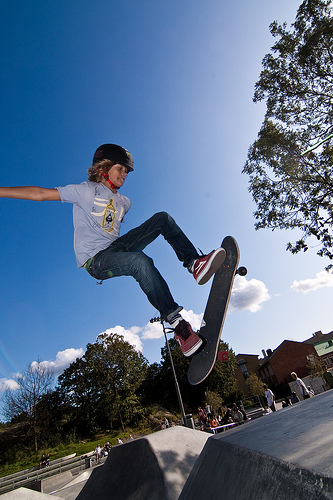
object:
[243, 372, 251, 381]
window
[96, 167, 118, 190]
chin strap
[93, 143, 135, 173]
helmet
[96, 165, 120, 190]
strap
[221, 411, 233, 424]
people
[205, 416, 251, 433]
bleachers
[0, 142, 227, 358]
boy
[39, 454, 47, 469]
person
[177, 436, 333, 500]
skateboard ramp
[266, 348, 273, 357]
chimney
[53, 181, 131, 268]
blue teeshirt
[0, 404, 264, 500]
stands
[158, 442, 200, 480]
shadow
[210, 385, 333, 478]
ramp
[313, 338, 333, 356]
roof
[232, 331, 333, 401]
building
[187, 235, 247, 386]
skate board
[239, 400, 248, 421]
people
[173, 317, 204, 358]
sneaker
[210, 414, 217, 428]
person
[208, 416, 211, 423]
orange shirt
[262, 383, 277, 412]
person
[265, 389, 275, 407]
shirt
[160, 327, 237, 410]
trees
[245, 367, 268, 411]
trees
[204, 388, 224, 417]
trees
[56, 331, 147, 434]
trees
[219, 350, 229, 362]
wheel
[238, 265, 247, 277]
wheel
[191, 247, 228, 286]
skate shoes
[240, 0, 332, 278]
tree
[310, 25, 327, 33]
green leaves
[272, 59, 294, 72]
green leaves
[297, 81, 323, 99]
green leaves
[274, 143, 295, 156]
green leaves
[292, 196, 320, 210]
green leaves